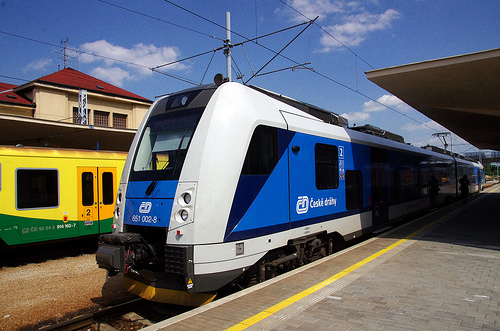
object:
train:
[92, 72, 481, 308]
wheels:
[0, 243, 32, 268]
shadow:
[375, 190, 500, 254]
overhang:
[363, 51, 500, 151]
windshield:
[129, 106, 207, 172]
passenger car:
[0, 145, 129, 251]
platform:
[132, 183, 499, 330]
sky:
[1, 0, 497, 153]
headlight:
[180, 210, 188, 221]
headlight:
[184, 193, 192, 204]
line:
[219, 185, 500, 331]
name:
[309, 197, 337, 209]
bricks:
[371, 305, 392, 313]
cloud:
[312, 9, 402, 57]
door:
[78, 167, 118, 235]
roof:
[14, 66, 152, 104]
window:
[313, 141, 342, 191]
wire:
[165, 0, 438, 132]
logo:
[296, 195, 309, 214]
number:
[86, 209, 91, 216]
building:
[0, 67, 152, 131]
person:
[459, 174, 470, 203]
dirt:
[1, 252, 109, 331]